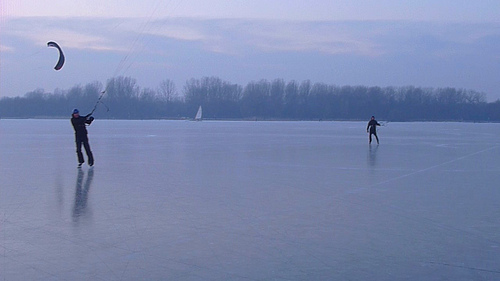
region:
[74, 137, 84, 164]
the leg of the skater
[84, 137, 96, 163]
the leg of the skater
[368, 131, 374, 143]
the leg of the skater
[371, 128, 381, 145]
the leg of the skater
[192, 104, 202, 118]
the white sail of the sailboat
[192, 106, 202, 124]
the sailboat on ice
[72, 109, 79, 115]
the head of the person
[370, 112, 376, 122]
the head of the person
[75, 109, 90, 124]
the arm of the person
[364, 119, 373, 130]
the arm of the person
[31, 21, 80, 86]
the kite is curved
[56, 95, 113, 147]
person wearing a black shirt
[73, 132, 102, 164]
person wearing black pants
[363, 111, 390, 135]
person has arm extended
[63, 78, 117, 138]
person holding on to bar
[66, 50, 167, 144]
string attached to bar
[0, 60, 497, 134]
trees line the background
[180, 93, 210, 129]
this is a boat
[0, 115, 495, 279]
A frozen lake.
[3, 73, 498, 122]
Line of trees at the edge of a lake.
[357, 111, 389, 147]
A person on a frozen lake.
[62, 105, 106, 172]
A person ice skating.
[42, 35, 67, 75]
A kite in the air.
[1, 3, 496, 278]
A winter day.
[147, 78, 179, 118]
Tree with no leaves.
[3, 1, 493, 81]
Greyish-blue sky with white clouds.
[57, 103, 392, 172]
Two people skating on a lake.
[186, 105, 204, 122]
Sailboat on a lake.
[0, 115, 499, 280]
lake of water turned to ice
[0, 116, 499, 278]
iced up body of water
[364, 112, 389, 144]
person standing on a frozen lake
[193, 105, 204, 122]
white sailboat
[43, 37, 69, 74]
blue kite in the air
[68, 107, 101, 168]
person holding on to a rope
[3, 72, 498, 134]
line of trees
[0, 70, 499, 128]
trees surrounding the lake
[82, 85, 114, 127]
rope in a person's hands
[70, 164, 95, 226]
reflection of the closer person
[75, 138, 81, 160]
the leg of a person skating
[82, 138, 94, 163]
the leg of a person skating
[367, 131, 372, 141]
the leg of a person skating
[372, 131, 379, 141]
the leg of a person skating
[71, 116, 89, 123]
the arm of a person skating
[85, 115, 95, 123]
the arm of a person skating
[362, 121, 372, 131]
the arm of a person skating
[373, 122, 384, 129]
the arm of a person skating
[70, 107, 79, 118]
the head of a person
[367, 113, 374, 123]
the head of a person